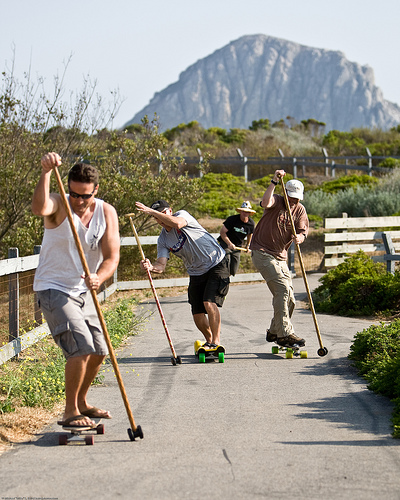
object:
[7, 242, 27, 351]
wooden post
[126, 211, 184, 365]
wooden push pole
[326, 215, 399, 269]
wooden fence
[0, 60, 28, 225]
green bush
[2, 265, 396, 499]
skating path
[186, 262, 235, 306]
brown shorts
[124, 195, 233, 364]
man skateboarding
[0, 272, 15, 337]
small fence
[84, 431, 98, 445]
colorful wheels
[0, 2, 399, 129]
pristine gray sky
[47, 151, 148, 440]
pole with wheels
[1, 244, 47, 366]
wooden barricade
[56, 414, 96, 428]
man's flipflops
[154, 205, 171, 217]
man's sunglasses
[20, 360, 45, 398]
wild flowers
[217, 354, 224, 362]
green wheels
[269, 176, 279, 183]
black watch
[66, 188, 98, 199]
sunglasses on face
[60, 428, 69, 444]
red wheels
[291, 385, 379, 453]
shadows from shrubs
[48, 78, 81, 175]
tall trees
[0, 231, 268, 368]
fence made of wood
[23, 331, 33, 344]
yellow flowers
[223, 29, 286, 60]
curved top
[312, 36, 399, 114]
curves in mountain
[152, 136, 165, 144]
single leaf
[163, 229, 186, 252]
logo on tee shirt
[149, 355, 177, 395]
black spot in road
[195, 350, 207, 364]
wheels are green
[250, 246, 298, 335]
tan pants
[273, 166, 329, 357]
large stick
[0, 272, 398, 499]
paved path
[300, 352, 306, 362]
bright green wheels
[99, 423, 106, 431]
wheels are red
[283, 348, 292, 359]
wheels are yellow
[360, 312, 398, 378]
bushes on the side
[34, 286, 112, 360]
gray shorts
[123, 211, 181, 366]
pole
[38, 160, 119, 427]
man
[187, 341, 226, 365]
skateboard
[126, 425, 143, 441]
wheels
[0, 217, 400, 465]
dirt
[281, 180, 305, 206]
head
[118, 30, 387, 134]
mountain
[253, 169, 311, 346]
man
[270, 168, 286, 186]
hand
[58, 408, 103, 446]
skateboard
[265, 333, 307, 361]
skateboard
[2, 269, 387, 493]
path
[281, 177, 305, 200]
hat